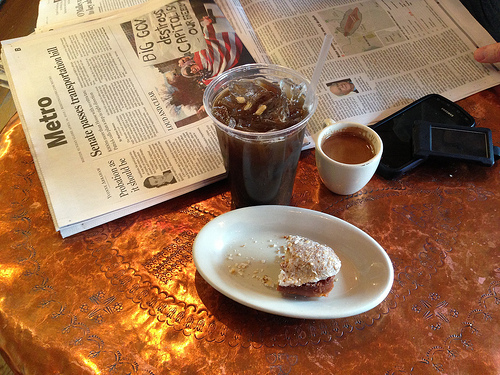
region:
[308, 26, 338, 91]
Clear straw in cup.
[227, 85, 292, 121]
Ice in soda in cup.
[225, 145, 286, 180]
Coca-cola soda in cup.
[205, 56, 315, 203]
Cup of soda on table.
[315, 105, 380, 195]
Cup of coffee on table.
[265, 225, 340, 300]
Half eaten muffin on plate.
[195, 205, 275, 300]
A white plate on table.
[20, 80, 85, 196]
Metro newspaper on table.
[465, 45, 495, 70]
Lady's pink fingernail over newspaper.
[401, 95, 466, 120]
Black phone case on table.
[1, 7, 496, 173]
open Metro newspaper on table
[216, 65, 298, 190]
iced drink in clear cup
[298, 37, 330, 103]
clear drinking straw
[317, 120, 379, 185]
small cup of hot espresso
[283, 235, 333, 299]
half eaten sandwich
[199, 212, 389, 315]
sandwich on a white oval plate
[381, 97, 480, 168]
black cell phone and case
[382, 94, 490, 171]
cell phone next to espresso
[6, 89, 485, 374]
red table cloth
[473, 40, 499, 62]
finger on top of newspaper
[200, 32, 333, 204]
iced drink in a plastic cup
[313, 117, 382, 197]
a small cup of coffee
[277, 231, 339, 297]
a half-eaten pastry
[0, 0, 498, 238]
an opened newspaper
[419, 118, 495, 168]
a small electronic device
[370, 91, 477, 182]
a black cell phone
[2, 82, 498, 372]
a gold-colored table cloth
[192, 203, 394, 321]
a white oval-shaped plate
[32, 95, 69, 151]
big black letters on the newspaper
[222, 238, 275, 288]
crumbs on the plate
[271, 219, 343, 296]
half eaten iced donut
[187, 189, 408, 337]
small round white plate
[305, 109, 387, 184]
small white mug with coffee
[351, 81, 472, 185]
black smartphone on table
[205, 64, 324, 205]
plastic cup with straw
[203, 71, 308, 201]
cola in plastic cup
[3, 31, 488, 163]
newspaper with color picture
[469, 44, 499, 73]
finger at edge of newspaper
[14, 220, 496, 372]
gold table with engraved design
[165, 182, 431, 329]
plate sitting on gold table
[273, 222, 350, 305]
piece of pastry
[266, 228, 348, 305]
half of pastry on a white dish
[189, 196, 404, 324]
white dish on a table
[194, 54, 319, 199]
glass of balck soda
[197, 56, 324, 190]
drink has ice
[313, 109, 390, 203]
small cup of coffee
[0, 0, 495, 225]
newspaper next to soda and a cup of coffee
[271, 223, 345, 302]
pastry has white top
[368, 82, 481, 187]
black cellphone on a table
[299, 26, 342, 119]
white straw in a cup of soda